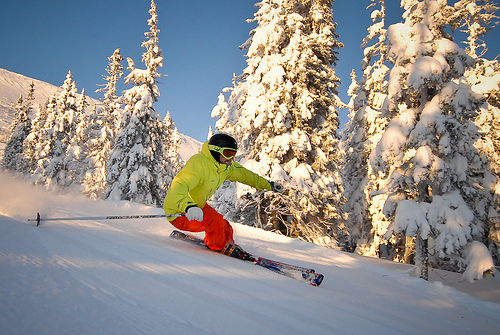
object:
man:
[153, 142, 285, 263]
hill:
[1, 69, 499, 334]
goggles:
[212, 143, 241, 162]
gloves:
[181, 175, 291, 225]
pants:
[166, 203, 248, 257]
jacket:
[162, 141, 277, 223]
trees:
[2, 0, 500, 275]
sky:
[1, 1, 499, 157]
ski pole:
[25, 202, 189, 230]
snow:
[2, 68, 499, 335]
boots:
[214, 232, 254, 264]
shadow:
[0, 217, 495, 334]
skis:
[166, 227, 333, 286]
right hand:
[177, 205, 206, 224]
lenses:
[222, 149, 247, 159]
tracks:
[29, 196, 289, 333]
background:
[2, 65, 498, 275]